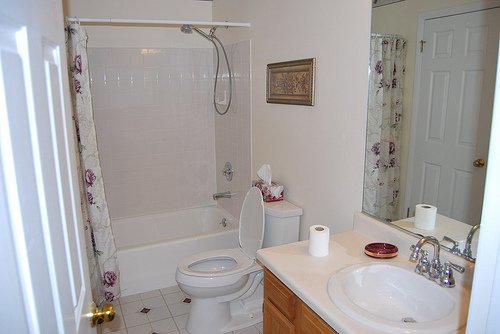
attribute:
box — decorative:
[252, 162, 283, 200]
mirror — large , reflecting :
[355, 0, 492, 277]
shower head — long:
[178, 17, 235, 55]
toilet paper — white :
[305, 223, 332, 260]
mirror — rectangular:
[349, 5, 476, 269]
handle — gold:
[73, 293, 140, 332]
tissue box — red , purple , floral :
[252, 163, 289, 203]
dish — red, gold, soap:
[362, 234, 401, 262]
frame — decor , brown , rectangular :
[258, 44, 325, 116]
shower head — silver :
[181, 26, 230, 114]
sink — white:
[335, 259, 385, 300]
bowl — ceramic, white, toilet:
[178, 247, 245, 299]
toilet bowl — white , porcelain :
[173, 246, 253, 332]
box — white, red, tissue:
[249, 165, 284, 205]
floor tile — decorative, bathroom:
[118, 293, 173, 326]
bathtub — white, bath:
[123, 197, 253, 289]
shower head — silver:
[181, 11, 209, 46]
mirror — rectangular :
[361, 0, 499, 260]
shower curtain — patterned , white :
[62, 20, 149, 305]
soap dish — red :
[364, 239, 401, 261]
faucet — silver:
[408, 234, 464, 287]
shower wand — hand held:
[180, 17, 219, 41]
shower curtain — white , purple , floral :
[44, 20, 155, 300]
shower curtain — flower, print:
[57, 10, 131, 307]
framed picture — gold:
[265, 57, 313, 105]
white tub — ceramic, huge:
[113, 205, 231, 250]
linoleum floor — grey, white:
[123, 298, 179, 328]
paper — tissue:
[257, 163, 276, 187]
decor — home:
[264, 57, 320, 114]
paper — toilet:
[306, 223, 330, 260]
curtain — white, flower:
[63, 23, 129, 306]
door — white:
[2, 1, 103, 331]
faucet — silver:
[211, 189, 232, 205]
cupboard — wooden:
[260, 268, 338, 331]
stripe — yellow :
[366, 250, 396, 258]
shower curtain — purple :
[62, 17, 122, 313]